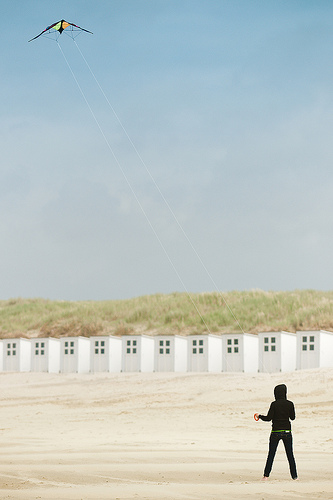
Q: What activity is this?
A: Flying a kite.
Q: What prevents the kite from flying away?
A: String.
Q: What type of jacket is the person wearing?
A: Hoodie.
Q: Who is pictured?
A: A young woman.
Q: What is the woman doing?
A: Flying a kite.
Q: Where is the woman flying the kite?
A: On the beach.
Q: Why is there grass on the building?
A: To hide them.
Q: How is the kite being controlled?
A: By the two strings.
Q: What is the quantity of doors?
A: 10.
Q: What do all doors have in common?
A: Color and 4 small windows.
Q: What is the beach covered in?
A: Sand.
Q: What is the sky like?
A: Clear and blue.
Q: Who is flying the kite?
A: A person.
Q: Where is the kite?
A: At beach.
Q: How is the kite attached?
A: By two strings.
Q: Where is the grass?
A: On hillside.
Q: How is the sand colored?
A: Golden.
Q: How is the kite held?
A: By white strings.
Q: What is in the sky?
A: A kite.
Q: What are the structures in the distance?
A: Changing rooms.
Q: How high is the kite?
A: Very high.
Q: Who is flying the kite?
A: A woman.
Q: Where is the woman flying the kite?
A: On the beach.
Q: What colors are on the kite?
A: Orange and yellow.